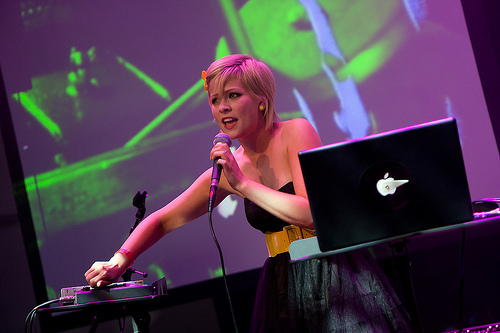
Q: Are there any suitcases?
A: No, there are no suitcases.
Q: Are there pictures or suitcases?
A: No, there are no suitcases or pictures.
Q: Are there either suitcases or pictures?
A: No, there are no suitcases or pictures.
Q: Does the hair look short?
A: Yes, the hair is short.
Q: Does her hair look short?
A: Yes, the hair is short.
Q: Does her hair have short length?
A: Yes, the hair is short.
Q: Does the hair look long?
A: No, the hair is short.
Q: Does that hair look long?
A: No, the hair is short.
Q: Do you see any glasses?
A: No, there are no glasses.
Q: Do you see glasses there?
A: No, there are no glasses.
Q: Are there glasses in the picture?
A: No, there are no glasses.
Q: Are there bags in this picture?
A: No, there are no bags.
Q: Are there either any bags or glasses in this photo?
A: No, there are no bags or glasses.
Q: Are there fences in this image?
A: No, there are no fences.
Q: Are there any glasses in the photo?
A: No, there are no glasses.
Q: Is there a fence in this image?
A: No, there are no fences.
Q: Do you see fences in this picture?
A: No, there are no fences.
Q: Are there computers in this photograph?
A: Yes, there is a computer.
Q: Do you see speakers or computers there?
A: Yes, there is a computer.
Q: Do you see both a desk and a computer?
A: No, there is a computer but no desks.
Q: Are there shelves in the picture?
A: No, there are no shelves.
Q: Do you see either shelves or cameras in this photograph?
A: No, there are no shelves or cameras.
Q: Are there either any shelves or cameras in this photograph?
A: No, there are no shelves or cameras.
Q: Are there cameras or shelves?
A: No, there are no shelves or cameras.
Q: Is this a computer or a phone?
A: This is a computer.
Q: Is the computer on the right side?
A: Yes, the computer is on the right of the image.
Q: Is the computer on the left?
A: No, the computer is on the right of the image.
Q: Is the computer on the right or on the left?
A: The computer is on the right of the image.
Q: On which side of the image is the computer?
A: The computer is on the right of the image.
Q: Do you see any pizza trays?
A: No, there are no pizza trays.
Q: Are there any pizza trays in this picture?
A: No, there are no pizza trays.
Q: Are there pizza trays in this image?
A: No, there are no pizza trays.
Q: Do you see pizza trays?
A: No, there are no pizza trays.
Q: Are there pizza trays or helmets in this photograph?
A: No, there are no pizza trays or helmets.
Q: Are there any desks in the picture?
A: No, there are no desks.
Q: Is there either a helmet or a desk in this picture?
A: No, there are no desks or helmets.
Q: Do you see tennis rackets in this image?
A: No, there are no tennis rackets.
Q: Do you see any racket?
A: No, there are no rackets.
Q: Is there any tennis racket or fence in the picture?
A: No, there are no rackets or fences.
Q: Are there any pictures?
A: No, there are no pictures.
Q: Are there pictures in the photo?
A: No, there are no pictures.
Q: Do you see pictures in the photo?
A: No, there are no pictures.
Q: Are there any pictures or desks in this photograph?
A: No, there are no pictures or desks.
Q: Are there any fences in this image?
A: No, there are no fences.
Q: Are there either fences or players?
A: No, there are no fences or players.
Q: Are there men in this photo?
A: No, there are no men.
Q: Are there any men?
A: No, there are no men.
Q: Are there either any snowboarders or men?
A: No, there are no men or snowboarders.